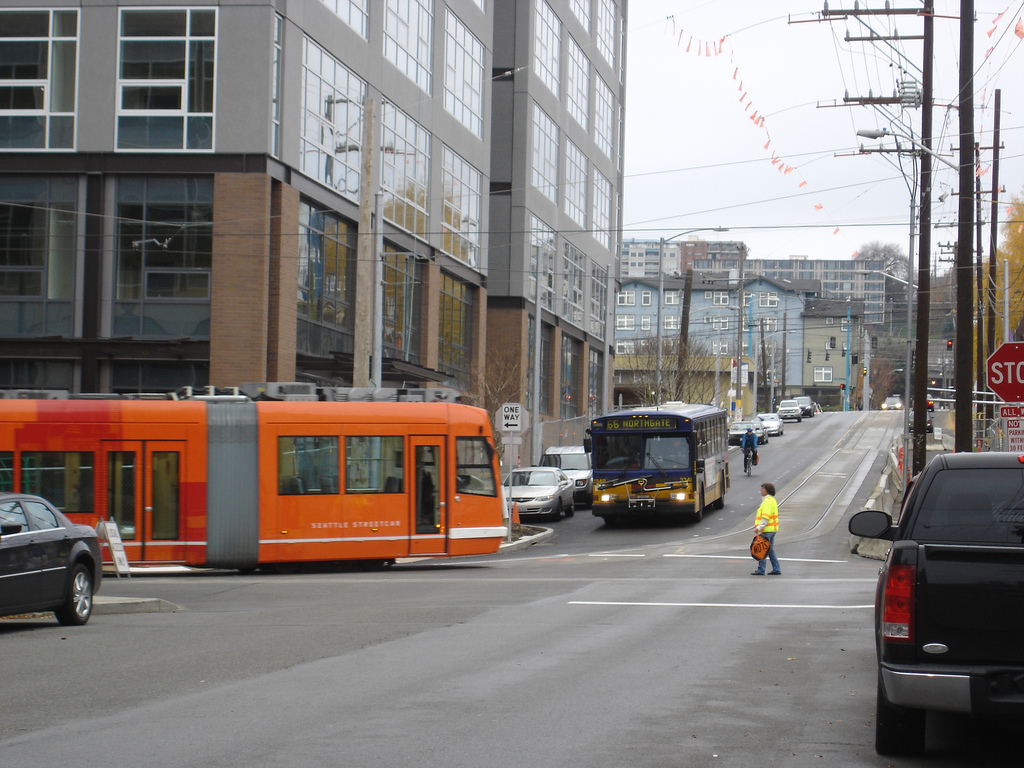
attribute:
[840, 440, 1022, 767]
truck — black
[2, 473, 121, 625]
car — black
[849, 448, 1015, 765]
truck — black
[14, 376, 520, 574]
bus — orange, white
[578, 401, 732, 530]
bus — blue, yellow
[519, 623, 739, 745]
road — dark grey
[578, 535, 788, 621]
crosswalk — white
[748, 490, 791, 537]
shirt — yellow, orange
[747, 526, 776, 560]
sign — orange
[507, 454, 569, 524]
car — parked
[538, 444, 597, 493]
car — parked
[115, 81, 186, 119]
window — glass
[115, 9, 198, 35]
window — glass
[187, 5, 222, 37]
window — glass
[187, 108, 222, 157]
window — glass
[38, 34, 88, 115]
window — glass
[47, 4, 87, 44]
window — glass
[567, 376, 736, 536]
bus — yellow, blue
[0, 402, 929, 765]
truck — black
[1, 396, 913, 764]
street — grey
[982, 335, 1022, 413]
stop sign — red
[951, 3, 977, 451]
light pole — tall, brown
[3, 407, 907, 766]
road — paved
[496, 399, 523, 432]
street sign — white, black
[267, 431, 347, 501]
window — glass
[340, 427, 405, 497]
window — glass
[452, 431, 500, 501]
window — glass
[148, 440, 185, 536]
window — glass